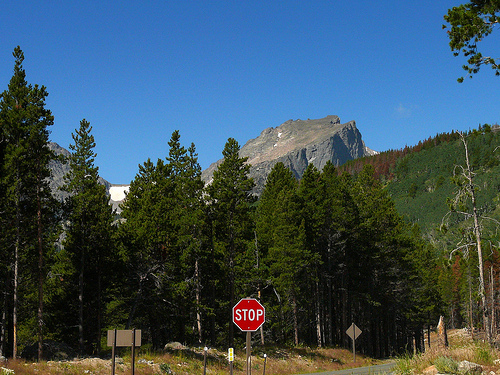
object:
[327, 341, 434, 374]
pavement path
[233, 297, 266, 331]
sign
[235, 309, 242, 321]
letter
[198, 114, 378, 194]
mountain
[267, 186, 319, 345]
pine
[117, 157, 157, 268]
pine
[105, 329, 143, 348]
sign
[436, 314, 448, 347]
stump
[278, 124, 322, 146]
granite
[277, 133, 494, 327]
hill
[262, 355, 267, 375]
pole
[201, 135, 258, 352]
tree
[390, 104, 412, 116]
cloud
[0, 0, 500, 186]
blue sky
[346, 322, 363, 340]
rhombus signboard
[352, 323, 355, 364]
pole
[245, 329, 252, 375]
pole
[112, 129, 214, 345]
tree